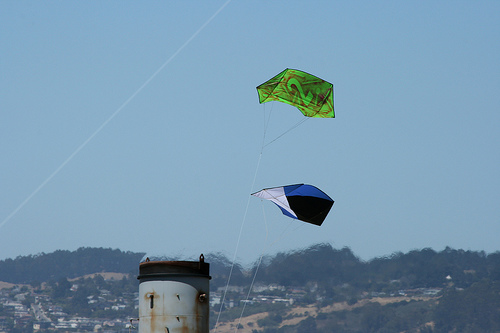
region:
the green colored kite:
[257, 67, 335, 121]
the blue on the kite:
[252, 182, 336, 225]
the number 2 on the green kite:
[257, 67, 337, 119]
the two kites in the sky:
[211, 67, 334, 329]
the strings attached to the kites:
[209, 67, 336, 331]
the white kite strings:
[0, 0, 234, 237]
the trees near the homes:
[0, 242, 498, 331]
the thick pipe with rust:
[137, 254, 213, 331]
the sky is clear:
[398, 153, 471, 216]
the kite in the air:
[246, 185, 345, 235]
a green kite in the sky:
[248, 66, 350, 131]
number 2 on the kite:
[286, 79, 315, 111]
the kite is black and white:
[254, 175, 335, 226]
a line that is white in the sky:
[70, 98, 133, 148]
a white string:
[243, 153, 256, 222]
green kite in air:
[267, 66, 341, 127]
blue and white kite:
[257, 172, 342, 234]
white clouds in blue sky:
[52, 67, 63, 82]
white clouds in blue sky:
[414, 98, 464, 153]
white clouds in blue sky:
[119, 127, 157, 165]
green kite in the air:
[223, 66, 368, 141]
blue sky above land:
[113, 100, 208, 176]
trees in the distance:
[346, 233, 456, 296]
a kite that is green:
[257, 65, 337, 140]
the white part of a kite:
[251, 172, 286, 222]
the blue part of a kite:
[278, 175, 332, 205]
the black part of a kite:
[287, 198, 337, 232]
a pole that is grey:
[114, 242, 229, 330]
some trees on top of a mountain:
[297, 231, 394, 315]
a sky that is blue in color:
[41, 9, 186, 143]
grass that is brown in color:
[220, 299, 262, 331]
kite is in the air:
[257, 65, 334, 121]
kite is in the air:
[249, 180, 334, 226]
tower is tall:
[136, 255, 212, 331]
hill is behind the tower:
[3, 240, 498, 332]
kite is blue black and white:
[251, 179, 336, 228]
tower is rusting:
[136, 252, 209, 332]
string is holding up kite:
[213, 100, 313, 330]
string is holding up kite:
[234, 197, 306, 329]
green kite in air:
[222, 52, 367, 132]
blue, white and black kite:
[233, 169, 345, 242]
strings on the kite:
[196, 210, 298, 301]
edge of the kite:
[232, 78, 284, 120]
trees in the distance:
[354, 222, 474, 304]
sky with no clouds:
[117, 120, 222, 210]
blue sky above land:
[110, 107, 234, 194]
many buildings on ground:
[46, 266, 131, 331]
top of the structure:
[121, 241, 224, 300]